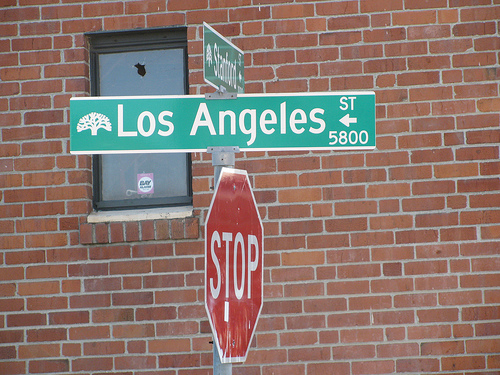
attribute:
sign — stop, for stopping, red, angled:
[203, 168, 266, 365]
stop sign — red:
[204, 166, 264, 363]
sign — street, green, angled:
[69, 89, 376, 156]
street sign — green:
[68, 91, 375, 154]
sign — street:
[203, 22, 244, 92]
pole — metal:
[212, 94, 232, 375]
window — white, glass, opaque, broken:
[85, 27, 191, 209]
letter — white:
[116, 103, 135, 137]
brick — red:
[295, 48, 338, 63]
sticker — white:
[223, 302, 231, 321]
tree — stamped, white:
[77, 112, 113, 136]